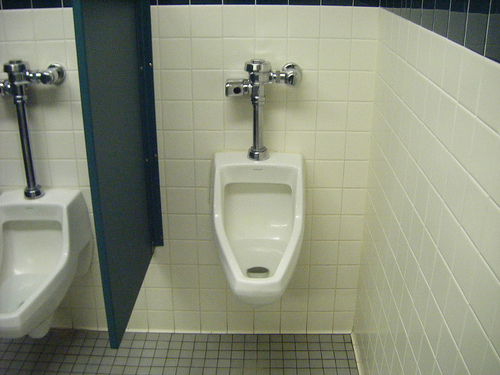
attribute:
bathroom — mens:
[16, 16, 473, 363]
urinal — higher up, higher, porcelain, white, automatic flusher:
[214, 72, 304, 292]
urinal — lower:
[0, 107, 71, 306]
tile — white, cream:
[157, 12, 374, 52]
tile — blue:
[425, 6, 499, 47]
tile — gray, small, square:
[13, 326, 352, 374]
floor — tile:
[24, 335, 349, 374]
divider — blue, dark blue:
[69, 15, 160, 291]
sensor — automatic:
[230, 84, 248, 101]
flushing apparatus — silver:
[228, 78, 271, 96]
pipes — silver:
[250, 95, 269, 158]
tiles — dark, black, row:
[401, 0, 499, 48]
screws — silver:
[146, 62, 156, 71]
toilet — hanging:
[217, 143, 307, 283]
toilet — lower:
[0, 201, 86, 343]